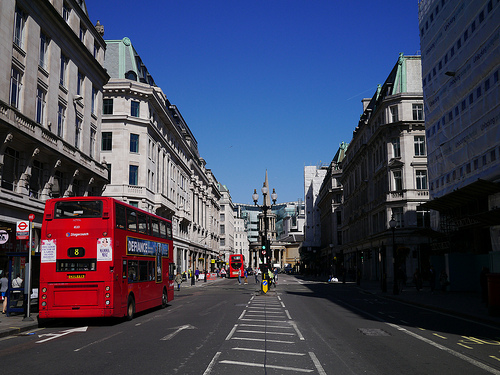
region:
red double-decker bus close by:
[39, 197, 176, 323]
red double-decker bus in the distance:
[229, 254, 243, 279]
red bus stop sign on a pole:
[16, 215, 33, 320]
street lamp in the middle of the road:
[253, 185, 275, 288]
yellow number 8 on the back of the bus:
[69, 247, 84, 255]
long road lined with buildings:
[4, 268, 499, 373]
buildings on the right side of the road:
[300, 5, 488, 317]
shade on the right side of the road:
[295, 265, 499, 336]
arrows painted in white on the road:
[37, 325, 193, 342]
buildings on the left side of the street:
[0, 1, 248, 278]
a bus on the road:
[22, 169, 246, 340]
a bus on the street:
[19, 123, 286, 339]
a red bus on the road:
[16, 151, 286, 371]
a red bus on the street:
[40, 143, 232, 327]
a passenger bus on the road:
[37, 170, 222, 373]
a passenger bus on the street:
[33, 156, 219, 351]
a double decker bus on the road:
[7, 152, 243, 357]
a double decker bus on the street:
[41, 143, 217, 314]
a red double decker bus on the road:
[42, 136, 240, 365]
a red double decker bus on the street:
[14, 134, 282, 373]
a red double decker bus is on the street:
[28, 176, 179, 325]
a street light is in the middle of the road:
[248, 168, 288, 315]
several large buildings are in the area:
[11, 5, 248, 318]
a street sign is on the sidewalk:
[5, 209, 37, 319]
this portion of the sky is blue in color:
[138, 13, 385, 77]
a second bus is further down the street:
[221, 250, 251, 286]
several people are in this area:
[183, 248, 314, 298]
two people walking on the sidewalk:
[1, 265, 31, 315]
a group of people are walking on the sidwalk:
[396, 261, 458, 301]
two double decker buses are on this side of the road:
[28, 178, 255, 328]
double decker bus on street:
[33, 192, 181, 325]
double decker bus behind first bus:
[228, 252, 245, 282]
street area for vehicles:
[189, 297, 348, 369]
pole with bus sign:
[13, 210, 36, 325]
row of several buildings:
[302, 0, 496, 307]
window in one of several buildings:
[123, 133, 143, 158]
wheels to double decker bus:
[119, 290, 177, 318]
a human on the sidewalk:
[8, 274, 23, 311]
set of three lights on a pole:
[244, 178, 284, 213]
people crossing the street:
[228, 266, 280, 287]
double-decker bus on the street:
[33, 197, 178, 324]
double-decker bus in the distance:
[227, 252, 245, 280]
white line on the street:
[204, 287, 326, 374]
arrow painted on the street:
[159, 320, 201, 341]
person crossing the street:
[173, 269, 184, 291]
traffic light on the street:
[259, 236, 269, 295]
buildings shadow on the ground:
[282, 281, 499, 341]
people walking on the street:
[231, 264, 261, 284]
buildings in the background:
[218, 163, 325, 275]